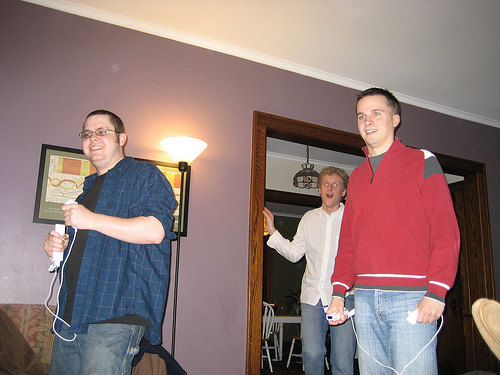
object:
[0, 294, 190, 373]
sofa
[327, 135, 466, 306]
shirt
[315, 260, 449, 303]
stripes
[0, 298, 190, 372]
couch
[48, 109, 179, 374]
guy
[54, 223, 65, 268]
controller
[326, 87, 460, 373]
guy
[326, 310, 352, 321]
controller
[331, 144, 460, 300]
sweater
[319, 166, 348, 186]
curlie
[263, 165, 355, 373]
man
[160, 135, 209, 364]
lamp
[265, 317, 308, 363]
table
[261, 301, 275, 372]
chairs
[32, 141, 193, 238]
picture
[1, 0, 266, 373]
wall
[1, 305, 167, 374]
comfy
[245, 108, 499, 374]
archway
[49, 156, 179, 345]
shirt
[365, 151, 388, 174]
shirt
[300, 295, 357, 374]
pants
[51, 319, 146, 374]
pants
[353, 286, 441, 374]
pants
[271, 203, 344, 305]
shirt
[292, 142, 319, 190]
lamp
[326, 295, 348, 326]
hand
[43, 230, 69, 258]
hand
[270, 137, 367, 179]
ceiling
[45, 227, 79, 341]
cord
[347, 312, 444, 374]
cord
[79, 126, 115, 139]
glasses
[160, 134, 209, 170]
light